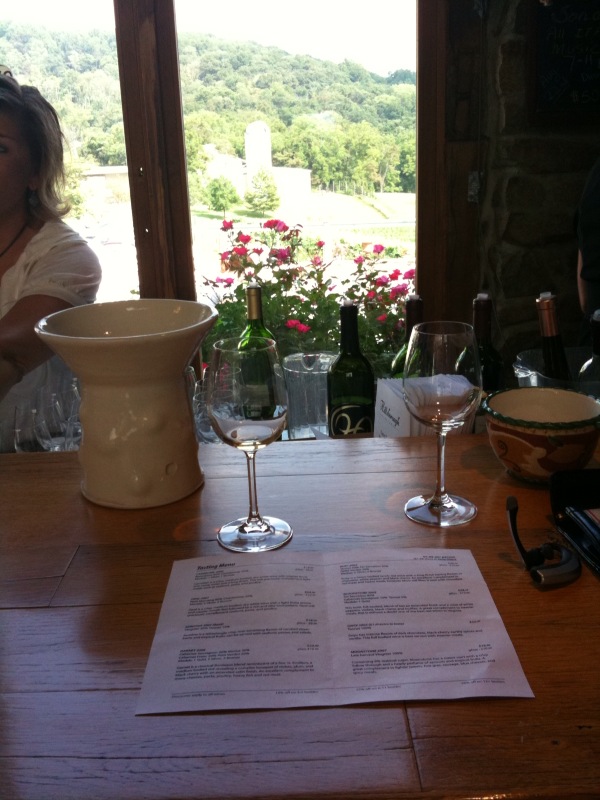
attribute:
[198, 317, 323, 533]
glass — clear, white, empty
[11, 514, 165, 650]
table — brown, wooden, neat, close, wood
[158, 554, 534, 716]
menu — white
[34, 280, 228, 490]
bucket — round, white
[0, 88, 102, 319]
woman — relaxing, sitting